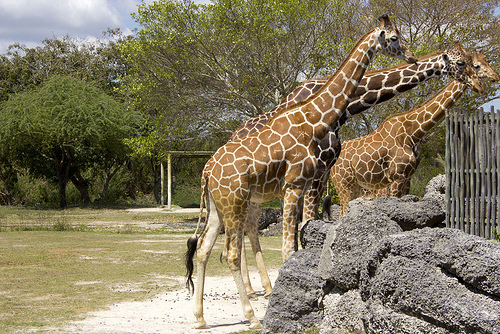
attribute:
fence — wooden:
[445, 112, 495, 232]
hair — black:
[182, 235, 199, 297]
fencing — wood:
[429, 117, 499, 222]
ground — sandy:
[95, 271, 249, 332]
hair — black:
[183, 235, 195, 298]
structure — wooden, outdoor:
[159, 149, 201, 206]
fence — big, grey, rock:
[260, 193, 497, 329]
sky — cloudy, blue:
[18, 6, 136, 46]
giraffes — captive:
[155, 10, 492, 331]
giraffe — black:
[181, 32, 407, 301]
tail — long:
[183, 168, 195, 278]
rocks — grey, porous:
[259, 172, 498, 332]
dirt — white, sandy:
[29, 268, 279, 331]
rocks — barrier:
[307, 192, 446, 322]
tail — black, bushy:
[185, 175, 204, 297]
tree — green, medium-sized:
[0, 67, 155, 207]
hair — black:
[168, 230, 213, 296]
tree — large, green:
[17, 65, 126, 217]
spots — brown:
[284, 122, 314, 143]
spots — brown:
[271, 113, 292, 136]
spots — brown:
[288, 110, 302, 133]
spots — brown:
[299, 102, 322, 125]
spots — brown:
[251, 137, 276, 166]